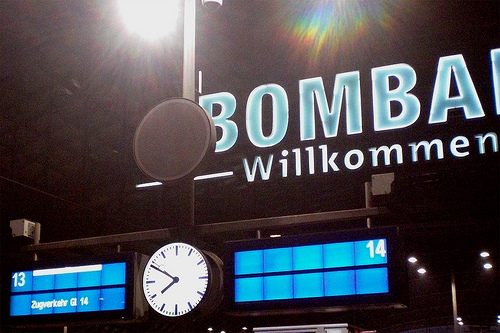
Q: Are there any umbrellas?
A: No, there are no umbrellas.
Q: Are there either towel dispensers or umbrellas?
A: No, there are no umbrellas or towel dispensers.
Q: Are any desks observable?
A: No, there are no desks.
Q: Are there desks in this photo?
A: No, there are no desks.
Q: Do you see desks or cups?
A: No, there are no desks or cups.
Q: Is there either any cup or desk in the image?
A: No, there are no desks or cups.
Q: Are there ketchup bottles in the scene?
A: No, there are no ketchup bottles.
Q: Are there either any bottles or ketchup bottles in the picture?
A: No, there are no ketchup bottles or bottles.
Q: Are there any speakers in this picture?
A: Yes, there is a speaker.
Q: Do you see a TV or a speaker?
A: Yes, there is a speaker.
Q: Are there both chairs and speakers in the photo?
A: No, there is a speaker but no chairs.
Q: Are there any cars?
A: No, there are no cars.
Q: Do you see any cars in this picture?
A: No, there are no cars.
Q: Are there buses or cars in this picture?
A: No, there are no cars or buses.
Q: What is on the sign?
A: The number is on the sign.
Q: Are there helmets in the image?
A: No, there are no helmets.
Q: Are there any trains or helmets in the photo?
A: No, there are no helmets or trains.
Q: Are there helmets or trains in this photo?
A: No, there are no helmets or trains.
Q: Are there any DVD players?
A: No, there are no DVD players.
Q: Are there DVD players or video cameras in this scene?
A: No, there are no DVD players or video cameras.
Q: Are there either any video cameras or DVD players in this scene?
A: No, there are no DVD players or video cameras.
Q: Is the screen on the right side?
A: No, the screen is on the left of the image.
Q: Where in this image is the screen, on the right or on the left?
A: The screen is on the left of the image.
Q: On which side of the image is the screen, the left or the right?
A: The screen is on the left of the image.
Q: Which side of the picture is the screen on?
A: The screen is on the left of the image.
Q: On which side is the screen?
A: The screen is on the left of the image.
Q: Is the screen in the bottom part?
A: Yes, the screen is in the bottom of the image.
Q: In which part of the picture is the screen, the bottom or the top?
A: The screen is in the bottom of the image.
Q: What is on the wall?
A: The screen is on the wall.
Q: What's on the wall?
A: The screen is on the wall.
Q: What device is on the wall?
A: The device is a screen.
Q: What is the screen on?
A: The screen is on the wall.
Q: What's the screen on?
A: The screen is on the wall.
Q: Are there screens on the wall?
A: Yes, there is a screen on the wall.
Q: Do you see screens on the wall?
A: Yes, there is a screen on the wall.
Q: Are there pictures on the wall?
A: No, there is a screen on the wall.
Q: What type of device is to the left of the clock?
A: The device is a screen.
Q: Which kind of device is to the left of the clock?
A: The device is a screen.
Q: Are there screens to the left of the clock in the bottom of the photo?
A: Yes, there is a screen to the left of the clock.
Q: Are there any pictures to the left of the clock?
A: No, there is a screen to the left of the clock.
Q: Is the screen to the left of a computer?
A: No, the screen is to the left of the clock.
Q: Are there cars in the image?
A: No, there are no cars.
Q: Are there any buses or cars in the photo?
A: No, there are no cars or buses.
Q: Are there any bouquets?
A: No, there are no bouquets.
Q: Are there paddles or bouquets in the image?
A: No, there are no bouquets or paddles.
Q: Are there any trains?
A: No, there are no trains.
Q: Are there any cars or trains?
A: No, there are no trains or cars.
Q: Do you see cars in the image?
A: No, there are no cars.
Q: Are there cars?
A: No, there are no cars.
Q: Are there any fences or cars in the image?
A: No, there are no cars or fences.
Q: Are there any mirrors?
A: No, there are no mirrors.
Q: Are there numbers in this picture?
A: Yes, there are numbers.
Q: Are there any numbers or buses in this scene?
A: Yes, there are numbers.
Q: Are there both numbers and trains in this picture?
A: No, there are numbers but no trains.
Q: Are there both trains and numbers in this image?
A: No, there are numbers but no trains.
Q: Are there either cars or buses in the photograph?
A: No, there are no cars or buses.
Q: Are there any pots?
A: No, there are no pots.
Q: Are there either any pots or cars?
A: No, there are no pots or cars.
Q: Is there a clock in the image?
A: Yes, there is a clock.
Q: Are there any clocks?
A: Yes, there is a clock.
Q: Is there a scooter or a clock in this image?
A: Yes, there is a clock.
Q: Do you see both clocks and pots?
A: No, there is a clock but no pots.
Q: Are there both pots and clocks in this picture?
A: No, there is a clock but no pots.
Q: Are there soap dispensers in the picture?
A: No, there are no soap dispensers.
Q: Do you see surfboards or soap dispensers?
A: No, there are no soap dispensers or surfboards.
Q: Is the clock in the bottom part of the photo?
A: Yes, the clock is in the bottom of the image.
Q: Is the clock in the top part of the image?
A: No, the clock is in the bottom of the image.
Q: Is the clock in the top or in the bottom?
A: The clock is in the bottom of the image.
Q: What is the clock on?
A: The clock is on the pole.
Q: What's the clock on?
A: The clock is on the pole.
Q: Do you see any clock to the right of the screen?
A: Yes, there is a clock to the right of the screen.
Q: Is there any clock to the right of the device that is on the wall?
A: Yes, there is a clock to the right of the screen.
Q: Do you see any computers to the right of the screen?
A: No, there is a clock to the right of the screen.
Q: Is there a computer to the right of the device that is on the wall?
A: No, there is a clock to the right of the screen.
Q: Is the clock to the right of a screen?
A: Yes, the clock is to the right of a screen.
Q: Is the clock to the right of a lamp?
A: No, the clock is to the right of a screen.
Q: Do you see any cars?
A: No, there are no cars.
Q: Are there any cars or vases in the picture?
A: No, there are no cars or vases.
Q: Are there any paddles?
A: No, there are no paddles.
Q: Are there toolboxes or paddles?
A: No, there are no paddles or toolboxes.